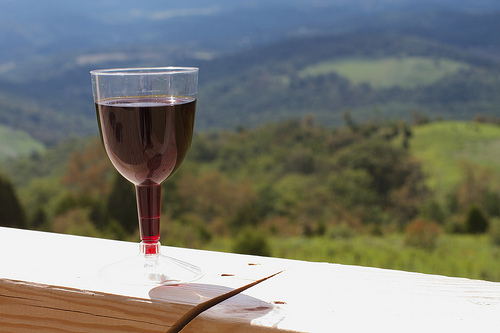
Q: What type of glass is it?
A: Wine.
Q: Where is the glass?
A: Ledge.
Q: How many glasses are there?
A: One.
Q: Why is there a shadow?
A: The sun.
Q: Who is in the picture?
A: No one.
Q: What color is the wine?
A: Red.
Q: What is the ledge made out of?
A: Wood.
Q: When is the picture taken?
A: Day time.